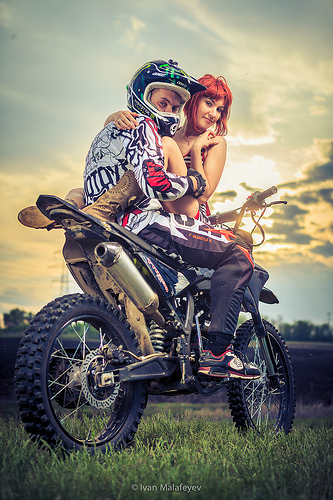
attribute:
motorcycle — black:
[13, 183, 312, 456]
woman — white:
[170, 74, 232, 223]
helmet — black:
[118, 52, 206, 137]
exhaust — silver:
[86, 235, 165, 330]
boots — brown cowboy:
[19, 169, 143, 249]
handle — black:
[249, 181, 279, 211]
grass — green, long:
[6, 389, 323, 499]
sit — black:
[48, 195, 188, 289]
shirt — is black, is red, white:
[78, 111, 195, 235]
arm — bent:
[189, 125, 232, 204]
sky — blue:
[8, 15, 126, 110]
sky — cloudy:
[239, 83, 331, 244]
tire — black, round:
[10, 286, 157, 464]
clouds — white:
[232, 5, 331, 126]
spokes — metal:
[49, 322, 123, 435]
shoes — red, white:
[194, 342, 271, 386]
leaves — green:
[3, 307, 25, 326]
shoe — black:
[195, 341, 262, 381]